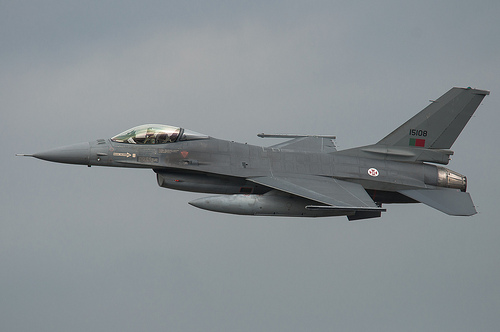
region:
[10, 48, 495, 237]
This is an airplane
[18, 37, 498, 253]
Not a commercial airplane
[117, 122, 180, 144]
You can see the pilot through the glass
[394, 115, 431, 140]
The number 15108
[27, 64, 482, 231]
Only the left side of the plane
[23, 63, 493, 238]
The is a jet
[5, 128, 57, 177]
The front of the plane is pointy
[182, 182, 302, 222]
There is a missile on the jet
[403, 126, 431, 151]
Green and red markings on the tail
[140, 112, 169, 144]
The pilot is wearing a helmet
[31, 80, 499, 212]
large grey fighter plane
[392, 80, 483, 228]
tail of a airplane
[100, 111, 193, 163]
cockpit of a airplane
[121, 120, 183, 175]
person flying a airplane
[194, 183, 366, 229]
missile on a aircraft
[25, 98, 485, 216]
military style aircraft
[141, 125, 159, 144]
pilot wearing a helmet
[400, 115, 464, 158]
numbers on the tail of aircraft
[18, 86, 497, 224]
large grey military airplane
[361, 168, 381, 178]
symbol on a aircraft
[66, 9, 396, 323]
Jet getting ready for fight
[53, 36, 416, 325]
Jet getting ready for fight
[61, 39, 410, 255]
Jet getting ready for fight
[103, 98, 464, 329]
Jet getting ready for fight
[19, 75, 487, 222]
this is a military plane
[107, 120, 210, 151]
a window over the cockpit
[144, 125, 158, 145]
a pilot in the cockpit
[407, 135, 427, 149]
a symbol on the tail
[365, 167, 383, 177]
a symbol on the plane body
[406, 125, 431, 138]
numbers on the tail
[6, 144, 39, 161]
the nose is pointed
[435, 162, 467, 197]
the end is shiny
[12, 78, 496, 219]
the plane is grey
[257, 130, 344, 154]
the wing is grey